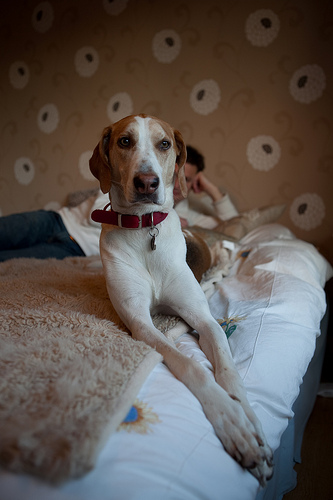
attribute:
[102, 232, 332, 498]
comforter — white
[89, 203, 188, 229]
collar — dog, brown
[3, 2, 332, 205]
wallpaper — flowered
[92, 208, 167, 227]
collar — brown, dog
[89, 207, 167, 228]
dog collar — brown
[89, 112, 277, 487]
dog — white and brown, relaxed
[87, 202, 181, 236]
collar — red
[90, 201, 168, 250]
dog collar — brown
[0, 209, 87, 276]
jeans — blue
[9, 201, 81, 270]
jeans — blue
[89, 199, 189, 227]
dog collar — brown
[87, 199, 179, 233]
collar — dark red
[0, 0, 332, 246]
wall — tan, white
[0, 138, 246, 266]
person — resting